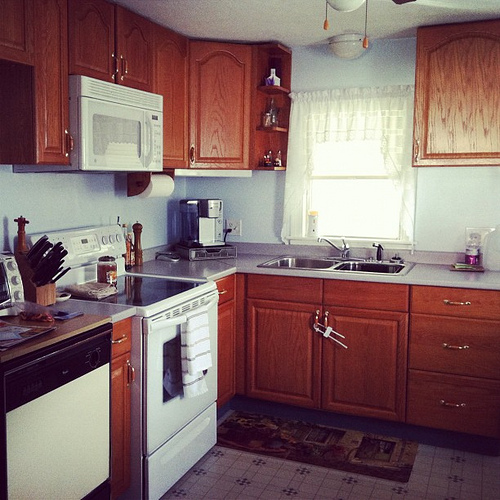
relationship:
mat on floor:
[215, 408, 419, 484] [201, 437, 464, 498]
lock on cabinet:
[298, 311, 339, 351] [252, 279, 413, 424]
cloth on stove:
[180, 305, 212, 400] [37, 227, 222, 472]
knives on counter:
[22, 233, 74, 290] [3, 287, 139, 357]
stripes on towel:
[178, 307, 213, 386] [179, 311, 215, 397]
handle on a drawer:
[443, 292, 473, 312] [408, 324, 495, 371]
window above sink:
[286, 89, 413, 244] [256, 257, 403, 277]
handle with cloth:
[150, 300, 221, 326] [180, 305, 212, 400]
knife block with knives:
[11, 215, 59, 307] [32, 233, 72, 292]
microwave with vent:
[15, 70, 163, 171] [69, 72, 166, 111]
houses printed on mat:
[232, 409, 409, 477] [209, 397, 433, 484]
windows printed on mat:
[357, 429, 396, 467] [209, 397, 433, 484]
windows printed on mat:
[297, 418, 338, 449] [209, 397, 433, 484]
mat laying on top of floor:
[215, 408, 419, 484] [185, 441, 485, 496]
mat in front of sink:
[215, 408, 419, 484] [255, 232, 417, 277]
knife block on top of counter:
[11, 215, 59, 307] [0, 299, 135, 361]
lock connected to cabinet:
[314, 322, 348, 350] [244, 295, 405, 419]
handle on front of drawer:
[435, 329, 479, 376] [404, 314, 494, 376]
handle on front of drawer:
[443, 300, 472, 306] [409, 286, 499, 321]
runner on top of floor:
[219, 409, 407, 474] [215, 464, 288, 497]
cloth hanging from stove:
[180, 305, 212, 400] [61, 225, 223, 479]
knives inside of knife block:
[27, 237, 69, 283] [13, 236, 78, 309]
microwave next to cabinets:
[12, 73, 163, 175] [35, 19, 191, 161]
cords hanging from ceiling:
[323, 3, 370, 50] [111, 0, 498, 44]